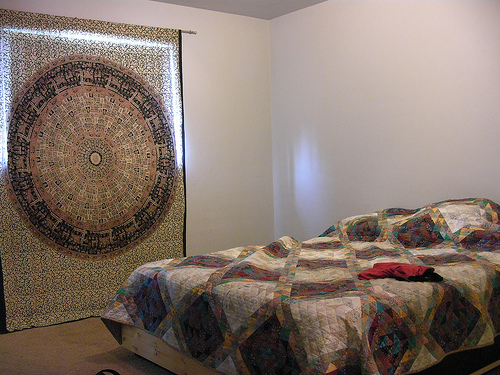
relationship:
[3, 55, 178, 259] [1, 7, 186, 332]
circle on drape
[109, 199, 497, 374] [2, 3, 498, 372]
bed in room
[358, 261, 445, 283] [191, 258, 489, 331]
cloth on bed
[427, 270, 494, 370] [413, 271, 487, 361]
triangles in square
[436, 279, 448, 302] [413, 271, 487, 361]
triangle in square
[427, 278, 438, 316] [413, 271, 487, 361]
triangle in square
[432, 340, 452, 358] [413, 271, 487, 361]
triangle in square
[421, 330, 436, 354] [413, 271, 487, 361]
triangle in square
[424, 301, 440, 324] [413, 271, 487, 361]
triangle in square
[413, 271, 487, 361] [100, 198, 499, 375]
square on bed cover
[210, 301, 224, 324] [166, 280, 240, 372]
triangle in square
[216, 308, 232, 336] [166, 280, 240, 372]
triangle in square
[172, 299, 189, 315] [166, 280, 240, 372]
triangle in square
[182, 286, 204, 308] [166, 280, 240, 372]
triangle in square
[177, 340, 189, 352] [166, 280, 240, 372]
triangle in square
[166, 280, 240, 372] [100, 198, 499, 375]
square on bed cover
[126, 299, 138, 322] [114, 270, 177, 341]
triangle in square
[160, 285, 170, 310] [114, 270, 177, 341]
triangle in square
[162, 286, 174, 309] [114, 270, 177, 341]
triangle in square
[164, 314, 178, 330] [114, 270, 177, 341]
triangle in square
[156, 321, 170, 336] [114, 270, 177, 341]
triangle in square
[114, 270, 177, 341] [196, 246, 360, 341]
square on bed cover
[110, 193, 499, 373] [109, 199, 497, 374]
patterned cover on bed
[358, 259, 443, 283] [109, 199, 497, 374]
cloth on bed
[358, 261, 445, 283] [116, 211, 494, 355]
cloth on bed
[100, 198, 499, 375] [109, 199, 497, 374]
bed cover covering bed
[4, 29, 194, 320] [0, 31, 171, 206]
curtain covering window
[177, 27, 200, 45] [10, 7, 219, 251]
rod hung above window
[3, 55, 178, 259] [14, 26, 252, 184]
circle on window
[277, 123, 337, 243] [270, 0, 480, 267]
light on wall